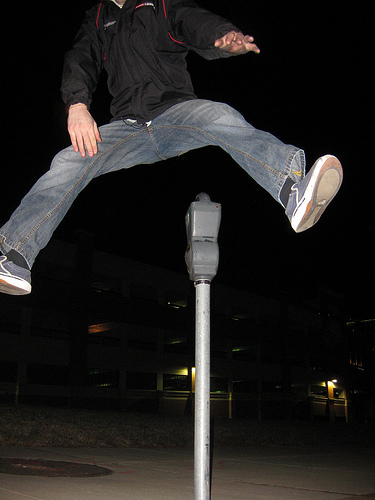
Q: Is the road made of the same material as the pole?
A: No, the road is made of cement and the pole is made of metal.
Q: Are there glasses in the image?
A: No, there are no glasses.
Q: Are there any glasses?
A: No, there are no glasses.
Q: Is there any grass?
A: Yes, there is grass.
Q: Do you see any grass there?
A: Yes, there is grass.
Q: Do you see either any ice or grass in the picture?
A: Yes, there is grass.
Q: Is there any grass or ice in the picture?
A: Yes, there is grass.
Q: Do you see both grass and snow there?
A: No, there is grass but no snow.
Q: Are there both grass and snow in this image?
A: No, there is grass but no snow.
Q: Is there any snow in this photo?
A: No, there is no snow.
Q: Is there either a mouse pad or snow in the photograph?
A: No, there are no snow or mouse pads.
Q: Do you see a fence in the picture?
A: No, there are no fences.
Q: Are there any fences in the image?
A: No, there are no fences.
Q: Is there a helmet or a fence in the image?
A: No, there are no fences or helmets.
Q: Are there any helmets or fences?
A: No, there are no fences or helmets.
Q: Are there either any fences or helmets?
A: No, there are no fences or helmets.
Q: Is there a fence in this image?
A: No, there are no fences.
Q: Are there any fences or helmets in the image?
A: No, there are no fences or helmets.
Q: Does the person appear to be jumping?
A: Yes, the person is jumping.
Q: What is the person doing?
A: The person is jumping.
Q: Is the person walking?
A: No, the person is jumping.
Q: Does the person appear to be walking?
A: No, the person is jumping.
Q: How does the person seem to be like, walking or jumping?
A: The person is jumping.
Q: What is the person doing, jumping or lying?
A: The person is jumping.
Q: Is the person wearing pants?
A: Yes, the person is wearing pants.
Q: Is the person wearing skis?
A: No, the person is wearing pants.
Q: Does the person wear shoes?
A: Yes, the person wears shoes.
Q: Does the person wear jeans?
A: No, the person wears shoes.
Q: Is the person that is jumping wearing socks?
A: Yes, the person is wearing socks.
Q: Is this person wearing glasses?
A: No, the person is wearing socks.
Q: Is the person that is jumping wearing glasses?
A: No, the person is wearing socks.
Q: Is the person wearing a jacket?
A: Yes, the person is wearing a jacket.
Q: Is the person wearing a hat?
A: No, the person is wearing a jacket.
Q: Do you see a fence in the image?
A: No, there are no fences.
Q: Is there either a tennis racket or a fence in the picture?
A: No, there are no fences or rackets.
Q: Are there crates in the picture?
A: No, there are no crates.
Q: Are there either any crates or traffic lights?
A: No, there are no crates or traffic lights.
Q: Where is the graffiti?
A: The graffiti is on the road.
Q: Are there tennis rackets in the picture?
A: No, there are no tennis rackets.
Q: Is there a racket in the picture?
A: No, there are no rackets.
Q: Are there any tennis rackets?
A: No, there are no tennis rackets.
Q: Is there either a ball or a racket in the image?
A: No, there are no rackets or balls.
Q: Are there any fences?
A: No, there are no fences.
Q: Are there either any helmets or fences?
A: No, there are no fences or helmets.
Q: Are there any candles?
A: No, there are no candles.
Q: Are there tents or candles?
A: No, there are no candles or tents.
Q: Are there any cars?
A: No, there are no cars.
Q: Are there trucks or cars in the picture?
A: No, there are no cars or trucks.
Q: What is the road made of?
A: The road is made of concrete.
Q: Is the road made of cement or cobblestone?
A: The road is made of cement.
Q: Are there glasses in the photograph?
A: No, there are no glasses.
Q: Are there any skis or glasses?
A: No, there are no glasses or skis.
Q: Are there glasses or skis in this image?
A: No, there are no glasses or skis.